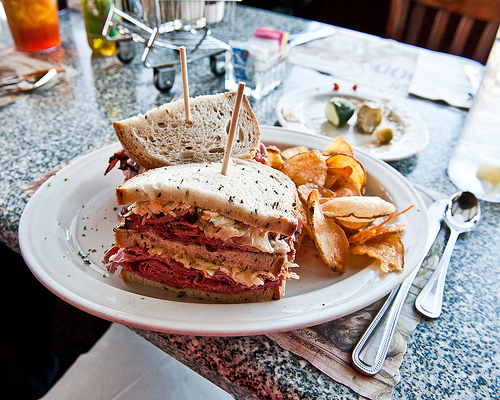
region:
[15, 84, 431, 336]
A sandwich and chips sitting on a plate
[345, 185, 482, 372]
A knife and spoon sitting next to a plate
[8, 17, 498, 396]
A marble patterned tabletop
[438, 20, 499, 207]
A beverage glass with fruit at the bottom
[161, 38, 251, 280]
Toothpicks used to hold the sandwich in place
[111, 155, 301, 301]
Half of a corned beef sandwich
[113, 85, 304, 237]
Rye bread with seeds used to make the sandwich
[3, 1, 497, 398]
food on marble restaurant table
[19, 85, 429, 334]
two half sandwiches on plate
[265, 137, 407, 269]
pile of potato chips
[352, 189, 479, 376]
silver spoon and knife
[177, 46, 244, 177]
wood pegs in bread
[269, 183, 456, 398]
edge of placemat on table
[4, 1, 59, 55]
bottom of glass with beverage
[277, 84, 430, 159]
plate with food items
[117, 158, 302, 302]
half of sliced snadwich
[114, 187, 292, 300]
three layers of bread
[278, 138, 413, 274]
pile of potato chips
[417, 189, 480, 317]
reflection on silver spoon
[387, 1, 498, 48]
back of wood chair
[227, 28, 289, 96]
sugar packets in container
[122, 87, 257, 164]
air holes in bread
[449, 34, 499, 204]
edge of water glass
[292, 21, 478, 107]
placemat with napkin on top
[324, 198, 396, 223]
dark edge of potato chip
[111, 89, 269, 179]
Smaller less visible half of a sandwich.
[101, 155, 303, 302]
Larger more visible half of a sandwich.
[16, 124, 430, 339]
Large round plate with two sandwich halves on it and chips.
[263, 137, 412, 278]
Side of kettle chips.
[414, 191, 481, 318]
A silver spoon.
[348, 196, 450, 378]
A long silver butter knife.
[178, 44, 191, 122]
Wooden toothpick in a less visible sandwich half.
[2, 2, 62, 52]
A cup of tea.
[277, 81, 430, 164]
Smaller round plate with pieces of veggie on it.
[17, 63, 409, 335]
a plate on a table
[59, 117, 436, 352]
a plate that is white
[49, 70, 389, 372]
a sandwich on a plate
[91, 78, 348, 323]
a sandwich cut in half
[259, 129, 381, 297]
chips on a plate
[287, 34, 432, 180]
vegetables on a plate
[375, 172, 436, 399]
a knife on a table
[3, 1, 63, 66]
a drink on a table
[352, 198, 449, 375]
shiny silver butter knife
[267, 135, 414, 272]
plain kettle chips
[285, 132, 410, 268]
Chips next to a sandwich.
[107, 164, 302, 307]
A large club sandwich.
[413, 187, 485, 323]
Spoon lying on the table.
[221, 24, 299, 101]
Sugar caddy on the table.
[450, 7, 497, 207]
Water glass on the table.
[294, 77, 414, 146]
Slices of fruit on plate.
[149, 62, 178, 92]
Wheel on a small cart.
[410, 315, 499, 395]
Black and white pattern on table.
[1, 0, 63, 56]
Glass of iced tea.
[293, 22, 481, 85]
Placemat on the table.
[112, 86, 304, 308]
large sandwich on three pieces of rye bread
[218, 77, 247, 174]
toothpick holding the sandwich together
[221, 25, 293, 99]
clear container filled with coffee sweetner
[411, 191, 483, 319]
spoon on the right side of the plate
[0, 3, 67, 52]
glass of iced tea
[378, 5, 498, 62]
back of a wood chair